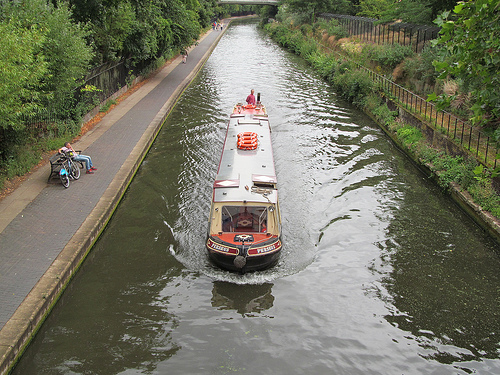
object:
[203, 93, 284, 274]
boat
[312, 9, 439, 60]
fence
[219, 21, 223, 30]
person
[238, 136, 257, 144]
lifeboats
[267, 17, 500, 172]
fence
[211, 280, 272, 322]
reflection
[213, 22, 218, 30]
people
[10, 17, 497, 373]
canal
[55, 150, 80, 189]
bicycle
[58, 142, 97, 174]
man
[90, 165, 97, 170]
red shoe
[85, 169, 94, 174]
red shoe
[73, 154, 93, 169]
blue jeans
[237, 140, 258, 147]
rings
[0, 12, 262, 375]
sidewalk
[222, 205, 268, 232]
window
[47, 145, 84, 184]
bench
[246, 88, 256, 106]
man